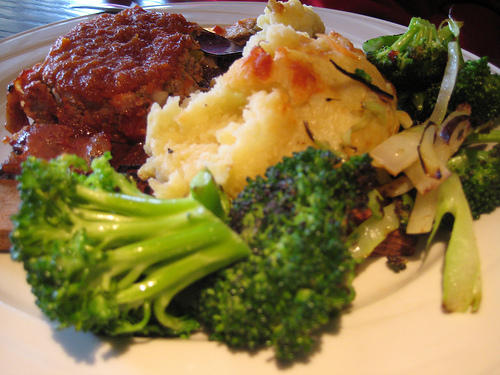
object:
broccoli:
[365, 13, 463, 112]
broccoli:
[448, 128, 500, 217]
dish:
[1, 1, 500, 375]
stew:
[8, 122, 117, 166]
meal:
[0, 3, 500, 374]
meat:
[8, 6, 204, 123]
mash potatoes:
[139, 0, 405, 201]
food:
[2, 2, 498, 358]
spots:
[243, 44, 281, 81]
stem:
[120, 187, 250, 292]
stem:
[391, 16, 439, 52]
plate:
[1, 1, 499, 371]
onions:
[372, 105, 471, 189]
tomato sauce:
[85, 20, 161, 75]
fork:
[70, 0, 248, 59]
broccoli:
[15, 148, 251, 346]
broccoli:
[191, 145, 397, 365]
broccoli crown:
[442, 153, 500, 218]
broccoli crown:
[8, 151, 145, 340]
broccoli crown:
[359, 41, 447, 90]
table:
[0, 1, 393, 59]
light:
[47, 0, 180, 17]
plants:
[9, 158, 250, 341]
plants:
[378, 16, 464, 87]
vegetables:
[357, 14, 498, 222]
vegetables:
[15, 142, 377, 366]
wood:
[2, 1, 61, 19]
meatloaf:
[14, 6, 206, 132]